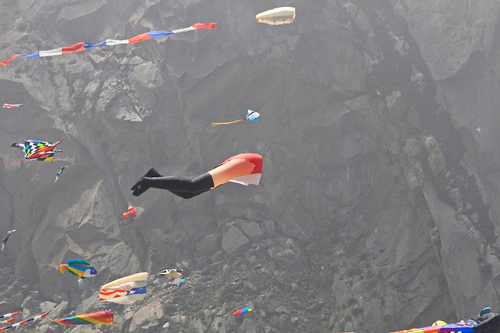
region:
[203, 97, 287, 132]
This is a kite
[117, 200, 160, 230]
This is a kite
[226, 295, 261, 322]
This is a kite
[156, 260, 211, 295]
This is a kite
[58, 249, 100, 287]
This is a kite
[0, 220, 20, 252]
This is a kite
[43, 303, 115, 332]
This is a kite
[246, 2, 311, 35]
This is a kite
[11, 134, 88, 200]
This is a kite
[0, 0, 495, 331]
kites flying in the sky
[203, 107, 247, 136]
short and narrow kite tail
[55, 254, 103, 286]
kite that looks like a fish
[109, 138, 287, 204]
red, black, and white kite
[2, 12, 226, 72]
red, white, and blue tail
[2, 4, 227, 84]
long tail of the kite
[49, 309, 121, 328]
rainbow on the kite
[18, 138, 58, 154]
black and white checkered pattern on the kite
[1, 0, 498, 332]
kites flying by the cliff side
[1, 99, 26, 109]
small kite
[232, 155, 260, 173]
A human shaped kite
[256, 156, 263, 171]
Red color on the kite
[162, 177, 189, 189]
Black color on kite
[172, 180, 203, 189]
Black human like kite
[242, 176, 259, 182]
White color on underside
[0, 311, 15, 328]
A group of kites flying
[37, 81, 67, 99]
Snow on a mountain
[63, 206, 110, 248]
Steep mountain sides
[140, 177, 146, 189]
Human like foot on the kite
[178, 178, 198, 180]
Light refelcting on the leg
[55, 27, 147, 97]
Kites in the photo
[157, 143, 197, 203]
Leggings on the photo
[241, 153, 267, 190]
Red clothings in the photo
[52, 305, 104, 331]
Rainbow colored kite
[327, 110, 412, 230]
A wall with rocks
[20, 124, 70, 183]
Kites flying in the photo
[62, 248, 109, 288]
Blue,green and yellow kite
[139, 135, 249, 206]
A painting of a woman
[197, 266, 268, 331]
rocks on the painting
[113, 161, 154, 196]
Boots on the photo